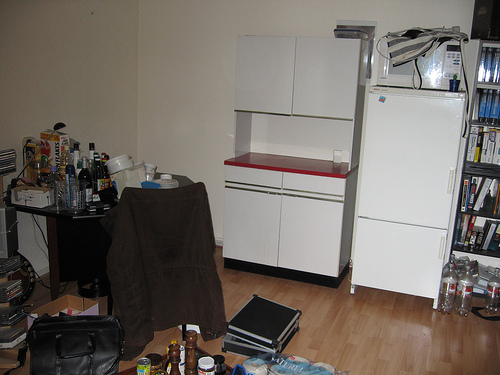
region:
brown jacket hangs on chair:
[113, 186, 222, 333]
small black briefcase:
[224, 297, 306, 354]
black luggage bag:
[27, 314, 124, 371]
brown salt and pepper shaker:
[167, 329, 201, 374]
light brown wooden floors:
[323, 298, 423, 366]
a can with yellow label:
[136, 357, 152, 372]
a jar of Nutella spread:
[196, 355, 216, 373]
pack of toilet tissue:
[244, 351, 343, 373]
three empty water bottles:
[439, 263, 496, 315]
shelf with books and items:
[463, 70, 498, 250]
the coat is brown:
[145, 231, 179, 274]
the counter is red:
[273, 156, 297, 166]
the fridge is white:
[388, 130, 413, 169]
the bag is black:
[58, 336, 93, 361]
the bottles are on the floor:
[442, 295, 467, 320]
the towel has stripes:
[393, 35, 413, 58]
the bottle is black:
[80, 169, 90, 184]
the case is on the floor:
[279, 313, 308, 343]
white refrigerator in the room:
[348, 82, 470, 229]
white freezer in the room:
[347, 214, 448, 312]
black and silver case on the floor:
[219, 292, 302, 361]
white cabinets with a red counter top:
[220, 31, 370, 288]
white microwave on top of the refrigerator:
[375, 39, 465, 91]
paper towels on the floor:
[238, 352, 345, 374]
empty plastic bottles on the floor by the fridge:
[438, 250, 499, 313]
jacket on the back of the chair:
[102, 180, 229, 360]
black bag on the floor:
[25, 312, 123, 374]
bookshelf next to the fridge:
[451, 38, 498, 259]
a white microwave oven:
[375, 33, 462, 90]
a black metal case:
[218, 291, 300, 361]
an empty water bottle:
[436, 263, 457, 313]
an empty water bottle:
[451, 262, 475, 317]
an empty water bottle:
[484, 265, 499, 314]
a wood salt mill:
[168, 340, 180, 373]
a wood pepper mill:
[185, 328, 197, 373]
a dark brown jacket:
[108, 187, 225, 357]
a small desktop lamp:
[6, 121, 67, 196]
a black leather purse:
[27, 315, 125, 374]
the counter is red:
[223, 145, 354, 182]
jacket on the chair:
[103, 182, 227, 355]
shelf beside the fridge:
[443, 43, 498, 283]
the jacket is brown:
[95, 180, 226, 362]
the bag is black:
[24, 314, 119, 373]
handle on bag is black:
[49, 332, 103, 360]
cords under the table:
[12, 209, 52, 296]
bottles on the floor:
[436, 248, 497, 319]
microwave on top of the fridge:
[372, 32, 469, 91]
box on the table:
[41, 124, 70, 168]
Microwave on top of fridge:
[373, 30, 464, 92]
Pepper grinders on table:
[155, 325, 209, 369]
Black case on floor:
[219, 288, 300, 357]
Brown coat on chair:
[96, 190, 236, 341]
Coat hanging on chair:
[102, 193, 227, 346]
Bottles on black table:
[57, 142, 118, 191]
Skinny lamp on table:
[11, 120, 75, 194]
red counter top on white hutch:
[223, 148, 355, 180]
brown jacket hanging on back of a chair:
[107, 179, 227, 362]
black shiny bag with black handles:
[18, 312, 131, 374]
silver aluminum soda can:
[135, 352, 151, 373]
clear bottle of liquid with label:
[439, 261, 456, 313]